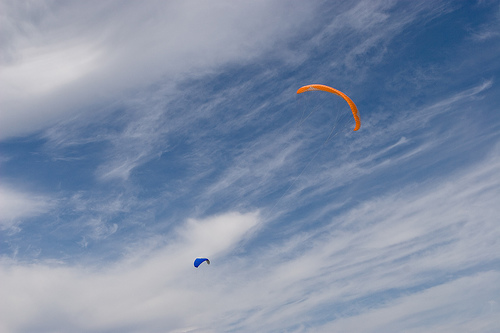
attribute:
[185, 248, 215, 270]
kite — blue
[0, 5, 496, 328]
sky — blue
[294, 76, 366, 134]
kite — orange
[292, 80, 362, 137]
kite — rounded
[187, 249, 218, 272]
kite — rounded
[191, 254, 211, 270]
float — blue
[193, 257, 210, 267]
sail — blue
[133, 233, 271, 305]
kite — small, blue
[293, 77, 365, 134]
sail — orange and white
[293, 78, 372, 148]
kite — orange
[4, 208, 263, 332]
cloud — blue and white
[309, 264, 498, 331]
cloud — blue and white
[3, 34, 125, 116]
cloud — blue and white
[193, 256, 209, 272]
klte — small, blue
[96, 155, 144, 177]
white cloud — thin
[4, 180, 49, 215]
cloud — small